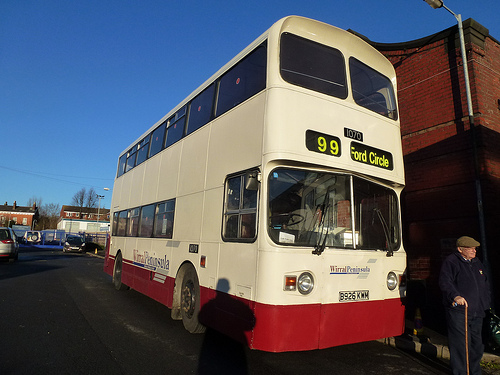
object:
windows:
[201, 32, 271, 120]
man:
[432, 222, 500, 375]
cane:
[450, 295, 476, 373]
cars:
[20, 228, 45, 247]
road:
[0, 238, 450, 375]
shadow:
[189, 271, 265, 375]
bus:
[101, 12, 416, 362]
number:
[315, 133, 329, 154]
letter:
[350, 145, 355, 159]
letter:
[353, 150, 358, 160]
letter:
[354, 150, 359, 160]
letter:
[362, 149, 369, 163]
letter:
[368, 150, 375, 165]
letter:
[374, 152, 377, 166]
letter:
[382, 153, 385, 168]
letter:
[385, 157, 391, 169]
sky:
[0, 0, 498, 219]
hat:
[452, 233, 482, 251]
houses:
[54, 200, 111, 228]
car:
[0, 226, 27, 266]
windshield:
[263, 159, 406, 257]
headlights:
[382, 264, 404, 293]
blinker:
[282, 271, 300, 293]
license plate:
[336, 289, 370, 303]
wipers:
[314, 185, 337, 258]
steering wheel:
[277, 208, 308, 230]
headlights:
[296, 266, 317, 298]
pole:
[447, 15, 495, 296]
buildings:
[1, 197, 42, 240]